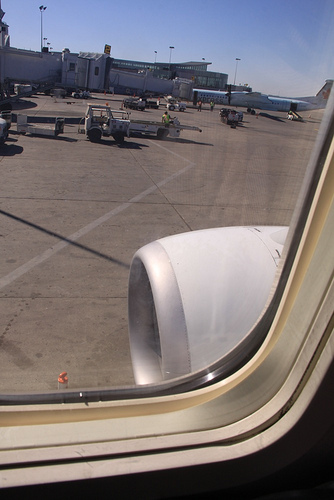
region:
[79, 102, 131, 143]
Small white runway vehicle that resembles a jeep.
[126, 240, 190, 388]
Silver frame on the outside of a plane engine.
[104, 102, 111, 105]
Orange light on top of a vehicle.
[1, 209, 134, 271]
Black shadow of a pole.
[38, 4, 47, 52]
A tall skinny light post off to the left with two lights on top.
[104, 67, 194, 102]
Long jetbridge that is connected to the plane to walk in.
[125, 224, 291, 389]
Large white and silver engine.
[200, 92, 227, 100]
Small windows on a nearby plane.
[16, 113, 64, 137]
Luggage cart sitting on a runway behind a jeep looking vehicle.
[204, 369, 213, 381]
White reflection spot on the window of a plane.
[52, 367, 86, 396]
the cone is orange and white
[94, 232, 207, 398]
silver trim of the engine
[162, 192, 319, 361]
white part of the engine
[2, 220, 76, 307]
white line on the road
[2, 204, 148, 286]
black line on the road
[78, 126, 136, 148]
wheels on the small vehicle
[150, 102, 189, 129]
person wearing a reflective vest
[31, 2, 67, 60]
large silver pole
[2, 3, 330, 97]
the blue and cloudless sky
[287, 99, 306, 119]
door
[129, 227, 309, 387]
White airplane engine on plane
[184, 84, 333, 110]
2nd airplane at terminal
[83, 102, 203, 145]
airport auxillary luggage car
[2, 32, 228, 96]
Airport buildings behind planes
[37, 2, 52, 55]
lamp post on top of airport building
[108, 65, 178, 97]
passenger tunnel connected to plane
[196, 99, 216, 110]
airport workers walking around in vests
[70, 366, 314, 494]
interior section of airplane window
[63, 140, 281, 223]
gray concrete tarmac with white lines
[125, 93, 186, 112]
airport support vehicles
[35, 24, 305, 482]
ground view from plane window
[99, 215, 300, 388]
window in front of plane engine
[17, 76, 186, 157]
service vehicles and carts spread out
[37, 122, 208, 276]
bent and faint white line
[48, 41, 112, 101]
small white building with windows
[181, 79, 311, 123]
airplane with open doors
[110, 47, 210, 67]
curved roof on airport building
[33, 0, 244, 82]
double lights on tall poles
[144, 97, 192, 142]
employee standing by vehicle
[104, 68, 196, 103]
tunnel for passengers to connect to plane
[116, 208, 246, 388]
propeller of airplane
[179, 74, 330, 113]
white airplane at airport with red symbol on tail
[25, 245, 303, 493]
white window of airplane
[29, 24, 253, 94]
large airport terminal with tall windows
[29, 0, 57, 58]
tall airport lights over terminal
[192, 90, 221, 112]
people standing on runway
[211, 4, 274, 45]
bright clear blue sky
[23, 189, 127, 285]
white lines on airport runway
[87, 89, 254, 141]
support vehicles at airport